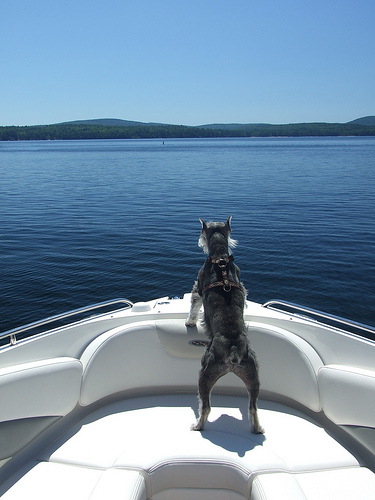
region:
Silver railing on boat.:
[265, 288, 374, 357]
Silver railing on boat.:
[25, 285, 156, 334]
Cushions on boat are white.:
[149, 412, 251, 490]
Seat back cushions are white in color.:
[111, 319, 296, 379]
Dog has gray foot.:
[240, 392, 279, 469]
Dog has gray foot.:
[189, 402, 223, 449]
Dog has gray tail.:
[224, 346, 267, 382]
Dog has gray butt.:
[210, 336, 279, 412]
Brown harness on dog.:
[215, 259, 237, 312]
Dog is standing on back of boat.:
[169, 267, 311, 396]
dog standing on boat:
[184, 207, 254, 436]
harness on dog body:
[204, 250, 242, 295]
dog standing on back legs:
[177, 305, 269, 442]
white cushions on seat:
[75, 423, 156, 492]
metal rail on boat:
[267, 296, 347, 325]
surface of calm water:
[112, 158, 209, 206]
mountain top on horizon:
[72, 113, 172, 137]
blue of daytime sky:
[259, 22, 340, 81]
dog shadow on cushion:
[191, 404, 269, 459]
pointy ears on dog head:
[191, 212, 237, 232]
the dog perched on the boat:
[190, 212, 260, 438]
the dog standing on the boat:
[186, 213, 266, 436]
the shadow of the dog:
[193, 395, 262, 459]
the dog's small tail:
[228, 350, 241, 364]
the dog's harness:
[203, 253, 245, 294]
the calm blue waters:
[77, 155, 182, 261]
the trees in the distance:
[8, 119, 374, 148]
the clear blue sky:
[49, 16, 301, 100]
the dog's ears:
[198, 213, 232, 228]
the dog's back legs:
[195, 362, 266, 436]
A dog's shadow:
[185, 396, 270, 460]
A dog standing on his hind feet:
[181, 211, 269, 442]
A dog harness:
[198, 251, 245, 300]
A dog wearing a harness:
[180, 211, 257, 344]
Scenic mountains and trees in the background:
[43, 111, 366, 145]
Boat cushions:
[50, 385, 370, 488]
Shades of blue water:
[40, 143, 184, 266]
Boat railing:
[1, 286, 132, 361]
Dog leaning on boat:
[166, 213, 266, 352]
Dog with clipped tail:
[182, 217, 273, 439]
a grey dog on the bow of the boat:
[184, 215, 265, 432]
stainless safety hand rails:
[0, 294, 130, 342]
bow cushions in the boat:
[0, 342, 189, 494]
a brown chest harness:
[198, 255, 240, 289]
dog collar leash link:
[219, 279, 227, 287]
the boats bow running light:
[167, 290, 174, 295]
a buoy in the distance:
[160, 136, 163, 143]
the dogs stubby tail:
[227, 344, 239, 365]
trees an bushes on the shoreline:
[1, 122, 373, 139]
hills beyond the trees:
[0, 113, 373, 133]